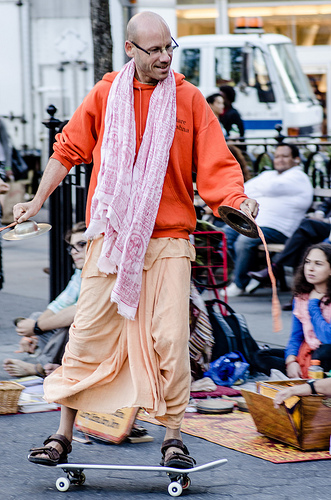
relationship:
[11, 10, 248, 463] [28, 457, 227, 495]
man rides skaterboard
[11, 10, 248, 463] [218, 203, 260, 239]
man holds cymbal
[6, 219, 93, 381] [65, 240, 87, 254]
man has glasses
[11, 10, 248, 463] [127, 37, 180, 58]
man wearing glasses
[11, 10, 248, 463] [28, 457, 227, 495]
man riding skateboard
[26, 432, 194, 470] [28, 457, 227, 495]
sandals on skateboard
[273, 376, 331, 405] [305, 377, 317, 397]
hand has wristwatch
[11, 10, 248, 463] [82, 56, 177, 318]
man wearing scarf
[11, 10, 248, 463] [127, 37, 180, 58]
guy has glasses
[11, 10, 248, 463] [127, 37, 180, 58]
man has glasses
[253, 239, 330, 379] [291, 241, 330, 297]
woman has hair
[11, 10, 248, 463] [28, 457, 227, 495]
man on a skateboard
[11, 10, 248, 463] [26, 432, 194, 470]
man wearing sandals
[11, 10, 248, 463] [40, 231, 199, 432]
man wearing skirt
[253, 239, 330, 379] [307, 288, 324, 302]
woman has a hand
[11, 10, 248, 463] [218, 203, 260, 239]
man holding cymbal